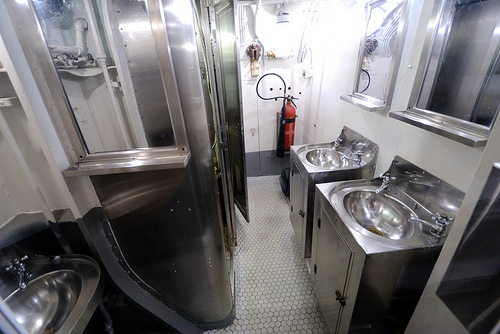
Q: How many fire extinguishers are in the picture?
A: One.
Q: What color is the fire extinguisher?
A: Red.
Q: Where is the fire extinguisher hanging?
A: On the wall.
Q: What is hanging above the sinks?
A: Mirrors.